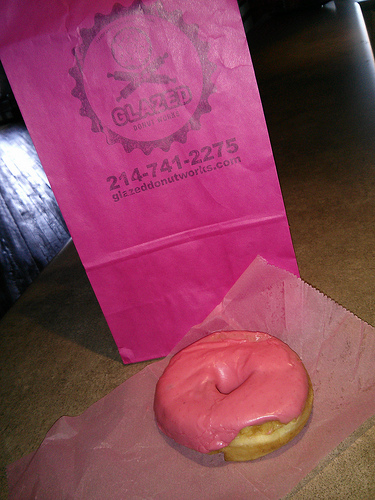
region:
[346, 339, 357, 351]
edge of paper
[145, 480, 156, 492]
part of a paper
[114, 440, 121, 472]
part of a pink paper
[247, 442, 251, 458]
part of a donut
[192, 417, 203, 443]
edge of a donut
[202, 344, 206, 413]
pink cream on a donut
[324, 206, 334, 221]
part of a table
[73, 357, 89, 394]
part of a surface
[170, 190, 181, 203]
part of a receipt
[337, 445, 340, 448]
side of a donut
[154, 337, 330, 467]
a pink glazed donut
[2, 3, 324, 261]
a pink donut bag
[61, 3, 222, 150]
a donut shop logo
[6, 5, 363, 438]
a pink donut bag and a pink glazed donut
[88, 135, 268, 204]
phone number and website for a donut shop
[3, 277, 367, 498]
pink glazed donut on waxed paper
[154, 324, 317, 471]
strawberry glazed donut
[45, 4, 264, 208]
donut shop logo with website and phone number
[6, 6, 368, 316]
pink donut bag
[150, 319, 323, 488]
pink glazed donut with too much glaze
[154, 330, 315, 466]
a strawberry icing doughnut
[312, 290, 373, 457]
wax paper wrapper for the donut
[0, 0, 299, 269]
a pink bag of the glazed donut works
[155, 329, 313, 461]
a pink glazed donut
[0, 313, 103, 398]
a brown carpet on the floor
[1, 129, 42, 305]
a reflection of light on the blinds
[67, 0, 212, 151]
a brand and logo of the donut business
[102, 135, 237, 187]
the phone number of the donut shop business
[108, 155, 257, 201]
the website of the doughnut shop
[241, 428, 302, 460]
the unglazed part of the donut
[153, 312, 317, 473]
Brown donut with pink icing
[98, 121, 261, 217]
Contact information for donut shop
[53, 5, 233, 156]
Donut shop graphic logo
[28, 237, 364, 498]
Donut on top of a piece of pink wax paper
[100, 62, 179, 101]
Two black rolling pins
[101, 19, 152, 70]
Black outline of a donut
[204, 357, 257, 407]
Hole in the donut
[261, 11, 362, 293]
Medium brown countertop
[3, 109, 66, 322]
Shiny wood floor in the background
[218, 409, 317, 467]
Edge of donut without icing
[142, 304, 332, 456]
the doughnut is brown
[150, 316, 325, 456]
the frosting is pink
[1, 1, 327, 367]
the bag is pink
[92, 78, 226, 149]
the bag says glazed donut works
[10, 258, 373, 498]
the doughnut is on waxed paper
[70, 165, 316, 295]
the paper bag has a crease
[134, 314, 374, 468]
the doughnut is pretty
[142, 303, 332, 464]
the doughnut is circular shaped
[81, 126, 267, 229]
the bag says 214-741-2275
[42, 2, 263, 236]
the print on the bag is black